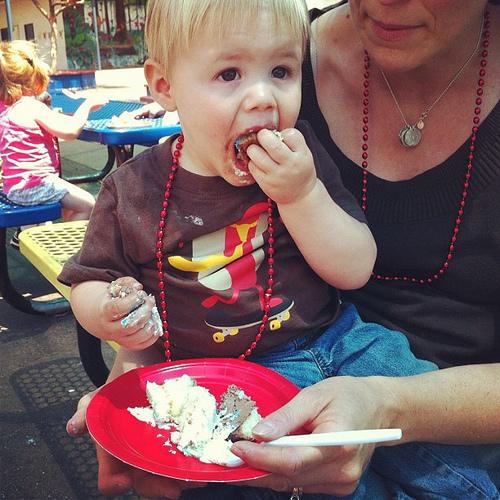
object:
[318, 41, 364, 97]
collar bone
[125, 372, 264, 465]
frosting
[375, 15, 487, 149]
locket necklace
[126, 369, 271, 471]
cake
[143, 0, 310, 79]
hair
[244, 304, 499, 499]
jeans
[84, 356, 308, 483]
bowl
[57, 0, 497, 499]
baby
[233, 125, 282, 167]
cake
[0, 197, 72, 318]
bench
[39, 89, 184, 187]
table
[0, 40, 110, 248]
girl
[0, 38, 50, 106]
hair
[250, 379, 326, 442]
thumb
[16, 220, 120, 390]
yellow bench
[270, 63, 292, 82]
eye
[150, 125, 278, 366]
necklace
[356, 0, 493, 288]
necklace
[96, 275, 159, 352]
hand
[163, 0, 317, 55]
blonde bangs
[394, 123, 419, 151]
locket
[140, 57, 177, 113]
ear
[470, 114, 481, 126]
beads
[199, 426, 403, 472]
fork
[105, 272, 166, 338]
ice cream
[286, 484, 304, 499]
wedding ring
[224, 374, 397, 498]
hand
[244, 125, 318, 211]
hand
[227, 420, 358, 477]
finger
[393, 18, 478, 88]
neck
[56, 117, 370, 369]
shirt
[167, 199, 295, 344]
cartoon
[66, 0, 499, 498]
woman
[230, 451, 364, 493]
finger